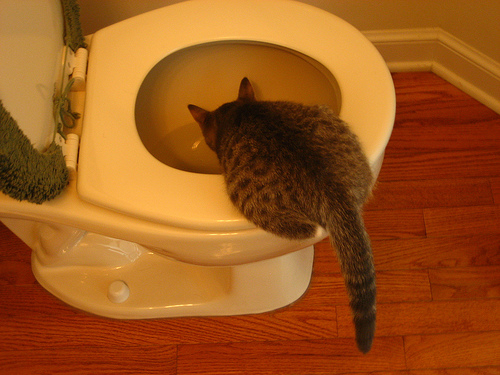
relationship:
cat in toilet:
[184, 75, 378, 257] [3, 54, 409, 331]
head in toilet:
[183, 77, 257, 153] [2, 0, 399, 330]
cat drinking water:
[187, 77, 376, 355] [147, 119, 225, 172]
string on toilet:
[51, 81, 94, 142] [2, 0, 399, 330]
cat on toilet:
[187, 77, 376, 355] [2, 82, 407, 334]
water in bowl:
[165, 121, 218, 170] [134, 37, 343, 174]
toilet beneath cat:
[2, 0, 399, 330] [187, 77, 376, 355]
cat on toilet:
[187, 77, 376, 355] [90, 16, 416, 311]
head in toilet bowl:
[183, 77, 257, 153] [78, 0, 395, 296]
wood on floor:
[403, 144, 498, 313] [361, 100, 485, 354]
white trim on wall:
[358, 19, 498, 116] [404, 20, 485, 72]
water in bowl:
[165, 121, 218, 170] [134, 43, 396, 324]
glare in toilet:
[182, 141, 196, 151] [2, 0, 399, 330]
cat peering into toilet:
[187, 77, 376, 355] [2, 0, 399, 330]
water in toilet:
[164, 128, 206, 166] [2, 0, 399, 330]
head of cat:
[169, 69, 264, 157] [179, 75, 418, 311]